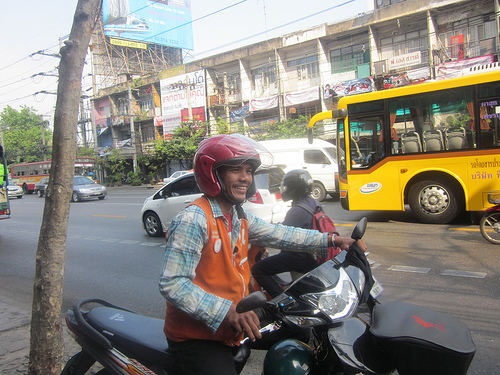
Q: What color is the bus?
A: Yellow.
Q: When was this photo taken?
A: During the day.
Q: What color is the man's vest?
A: Orange.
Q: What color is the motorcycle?
A: Black.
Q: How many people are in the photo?
A: 2.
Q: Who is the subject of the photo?
A: The man.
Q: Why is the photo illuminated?
A: Sunlight.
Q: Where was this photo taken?
A: On the street.